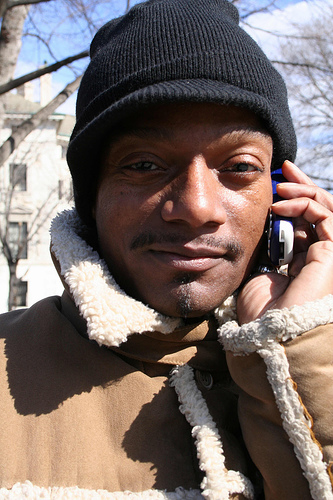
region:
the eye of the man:
[217, 152, 265, 176]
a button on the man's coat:
[194, 367, 214, 390]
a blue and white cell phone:
[261, 155, 296, 264]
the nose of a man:
[157, 145, 230, 230]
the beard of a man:
[170, 270, 195, 321]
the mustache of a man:
[128, 221, 251, 263]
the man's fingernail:
[270, 198, 288, 208]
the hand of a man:
[231, 157, 331, 333]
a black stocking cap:
[58, 0, 296, 223]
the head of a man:
[61, 0, 299, 324]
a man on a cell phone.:
[45, 25, 320, 341]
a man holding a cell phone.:
[49, 25, 320, 373]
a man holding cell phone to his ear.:
[32, 54, 312, 350]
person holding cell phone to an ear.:
[41, 48, 318, 356]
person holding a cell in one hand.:
[39, 48, 315, 350]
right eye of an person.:
[115, 152, 166, 191]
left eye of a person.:
[216, 140, 265, 198]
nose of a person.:
[160, 146, 226, 232]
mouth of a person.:
[146, 239, 235, 279]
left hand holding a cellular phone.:
[260, 146, 327, 296]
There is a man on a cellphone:
[27, 17, 331, 385]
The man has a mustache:
[22, 66, 328, 377]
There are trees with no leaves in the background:
[22, 48, 331, 321]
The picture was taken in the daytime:
[0, 0, 331, 331]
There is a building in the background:
[0, 7, 331, 274]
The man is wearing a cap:
[33, 1, 320, 221]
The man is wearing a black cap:
[16, 0, 326, 367]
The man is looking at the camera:
[38, 53, 328, 406]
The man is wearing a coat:
[0, 47, 331, 486]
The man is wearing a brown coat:
[4, 25, 329, 499]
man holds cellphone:
[248, 129, 312, 284]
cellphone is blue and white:
[254, 151, 302, 264]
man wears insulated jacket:
[22, 220, 331, 491]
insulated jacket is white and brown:
[0, 207, 332, 495]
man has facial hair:
[122, 219, 259, 323]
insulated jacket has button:
[172, 343, 239, 415]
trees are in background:
[3, 2, 325, 312]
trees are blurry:
[1, 1, 332, 305]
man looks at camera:
[91, 147, 276, 307]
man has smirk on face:
[85, 134, 280, 300]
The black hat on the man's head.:
[79, 12, 294, 167]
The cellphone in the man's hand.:
[266, 181, 290, 270]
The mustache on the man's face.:
[127, 226, 248, 257]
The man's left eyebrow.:
[114, 122, 162, 138]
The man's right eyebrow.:
[212, 121, 265, 145]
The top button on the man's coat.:
[189, 368, 210, 385]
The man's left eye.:
[117, 145, 164, 172]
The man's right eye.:
[220, 154, 267, 184]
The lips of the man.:
[146, 240, 226, 272]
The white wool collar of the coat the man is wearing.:
[44, 209, 165, 355]